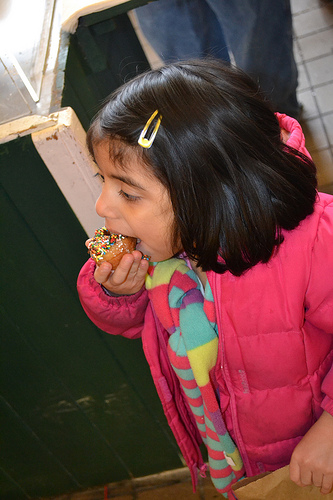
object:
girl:
[77, 59, 331, 496]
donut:
[88, 226, 141, 267]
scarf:
[139, 260, 244, 494]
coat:
[75, 107, 332, 498]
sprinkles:
[90, 225, 125, 259]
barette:
[135, 108, 167, 153]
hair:
[84, 57, 321, 275]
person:
[137, 3, 304, 126]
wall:
[0, 103, 229, 498]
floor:
[284, 0, 332, 195]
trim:
[30, 108, 108, 258]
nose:
[96, 188, 118, 217]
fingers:
[131, 255, 149, 287]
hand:
[286, 405, 333, 495]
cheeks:
[142, 211, 176, 251]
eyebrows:
[108, 175, 154, 202]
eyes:
[116, 188, 141, 200]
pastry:
[86, 224, 137, 273]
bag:
[229, 458, 332, 497]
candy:
[88, 227, 127, 249]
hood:
[271, 109, 314, 167]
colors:
[203, 387, 214, 403]